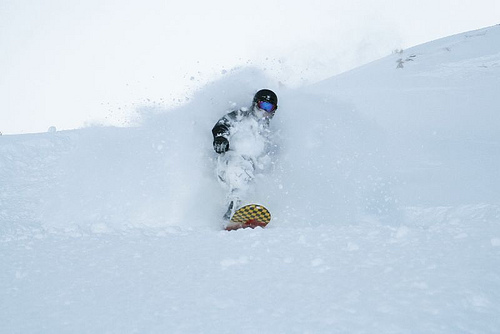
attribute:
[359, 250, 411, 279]
snow — white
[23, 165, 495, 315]
snow — White 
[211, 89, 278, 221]
man — Boarding , Snowboarding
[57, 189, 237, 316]
snow — White 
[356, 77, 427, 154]
snow — White 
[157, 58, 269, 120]
snow — White 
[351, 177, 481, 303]
snow — White 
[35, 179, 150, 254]
snow — White 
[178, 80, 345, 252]
person — Gloved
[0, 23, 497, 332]
snow — White 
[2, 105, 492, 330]
snow — White 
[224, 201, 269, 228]
snowboard — black, checkered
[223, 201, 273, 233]
snowboard — Yellow , Black 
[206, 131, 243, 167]
gloves — black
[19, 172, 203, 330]
snow — White 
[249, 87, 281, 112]
helmet — black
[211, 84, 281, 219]
snowboarder — Snowboarding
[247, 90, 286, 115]
helmet — On head 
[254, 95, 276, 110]
goggles — Blurry 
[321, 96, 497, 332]
snow — White 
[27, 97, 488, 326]
ground — Snowy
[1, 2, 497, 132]
sky — Blue 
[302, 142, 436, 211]
snow — White 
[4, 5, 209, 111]
sky — Blue 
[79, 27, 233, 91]
clouds — White 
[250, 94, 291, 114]
goggles — blue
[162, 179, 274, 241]
snowboard — Black , Yellow 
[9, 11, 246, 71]
sky — cloudy